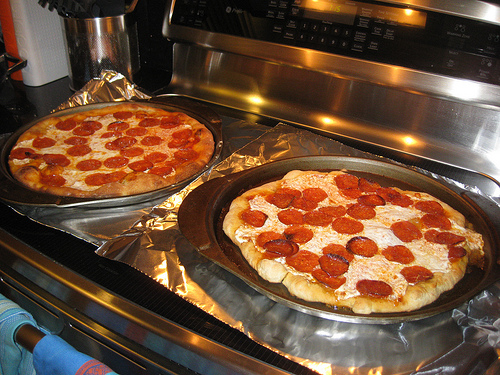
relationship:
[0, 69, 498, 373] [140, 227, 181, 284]
foil has wrinkle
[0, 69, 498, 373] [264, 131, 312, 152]
foil has wrinkle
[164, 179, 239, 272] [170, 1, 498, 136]
plate in stove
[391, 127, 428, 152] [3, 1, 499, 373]
light reflecting off stove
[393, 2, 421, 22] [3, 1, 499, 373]
light reflecting off stove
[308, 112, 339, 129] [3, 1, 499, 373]
light reflecting off stove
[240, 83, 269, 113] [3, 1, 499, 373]
light reflecting off stove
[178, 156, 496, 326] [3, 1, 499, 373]
plate on stove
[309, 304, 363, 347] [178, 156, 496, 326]
light on plate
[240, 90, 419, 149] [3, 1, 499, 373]
light on stove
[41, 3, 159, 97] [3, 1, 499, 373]
bottle near stove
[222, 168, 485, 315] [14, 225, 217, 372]
pizza on top of oven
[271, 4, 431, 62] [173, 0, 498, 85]
buttons on panel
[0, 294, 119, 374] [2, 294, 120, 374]
towel on handle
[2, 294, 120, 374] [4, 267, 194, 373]
handle of door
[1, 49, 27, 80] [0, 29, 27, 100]
handle of pan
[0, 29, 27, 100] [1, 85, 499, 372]
pan next to stove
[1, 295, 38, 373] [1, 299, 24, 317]
towel with stripe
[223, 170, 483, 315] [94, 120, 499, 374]
pizza on foil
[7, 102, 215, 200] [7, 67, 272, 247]
pizza on foil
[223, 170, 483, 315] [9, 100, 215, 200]
pizza side by side pizza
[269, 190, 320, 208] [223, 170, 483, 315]
pepperoni on pizza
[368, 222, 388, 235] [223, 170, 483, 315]
cheese on pizza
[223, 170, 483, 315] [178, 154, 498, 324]
pizza on pans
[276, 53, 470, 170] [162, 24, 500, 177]
buttons on buttons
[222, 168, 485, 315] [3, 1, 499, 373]
pizza on stove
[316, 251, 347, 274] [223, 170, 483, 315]
pepperoni on pizza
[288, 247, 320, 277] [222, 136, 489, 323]
pepperoni on pizza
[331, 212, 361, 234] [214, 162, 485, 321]
pepperoni on pizza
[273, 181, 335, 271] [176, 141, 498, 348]
pepperoni on pizza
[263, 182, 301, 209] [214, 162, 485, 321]
pepperoni on pizza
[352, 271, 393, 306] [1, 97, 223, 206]
pepperoni on pizza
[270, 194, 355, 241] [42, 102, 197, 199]
pepperoni piece on pizza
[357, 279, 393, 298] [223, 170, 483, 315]
pepperoni on pizza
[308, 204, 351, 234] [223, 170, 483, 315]
red pepperoni on pizza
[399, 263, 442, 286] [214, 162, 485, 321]
pepperoni on pizza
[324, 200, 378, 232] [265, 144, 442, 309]
pepperoni on pizza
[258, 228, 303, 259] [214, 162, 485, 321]
pepporoni on pizza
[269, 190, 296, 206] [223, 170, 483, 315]
pepperoni on pizza